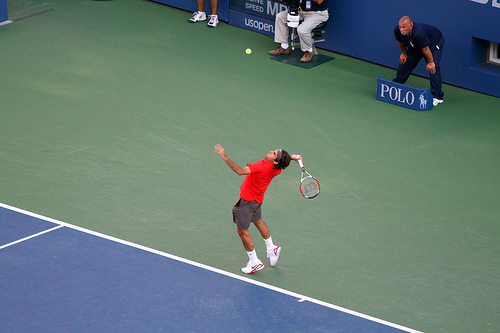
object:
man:
[390, 15, 445, 106]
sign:
[373, 75, 434, 111]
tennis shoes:
[188, 11, 207, 23]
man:
[266, 1, 330, 63]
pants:
[273, 10, 330, 50]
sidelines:
[148, 0, 496, 112]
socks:
[243, 247, 260, 262]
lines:
[0, 200, 422, 331]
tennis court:
[158, 77, 376, 126]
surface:
[58, 61, 152, 213]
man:
[213, 142, 305, 274]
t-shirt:
[238, 157, 283, 205]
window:
[487, 40, 499, 64]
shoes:
[240, 258, 265, 274]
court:
[0, 0, 499, 332]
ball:
[243, 48, 252, 54]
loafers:
[267, 47, 291, 56]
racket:
[298, 154, 321, 200]